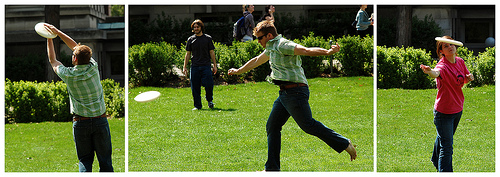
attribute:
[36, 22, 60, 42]
frisbee — plastic, white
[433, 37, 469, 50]
frisbee — white, yellow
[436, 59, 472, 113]
shirt — pink, red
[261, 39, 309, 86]
shirt — green, white, green plaid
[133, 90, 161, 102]
frisbee — white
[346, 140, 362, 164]
foot — bare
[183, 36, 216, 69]
shirt — black, dark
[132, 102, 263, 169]
grass — green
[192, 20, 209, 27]
hair — brown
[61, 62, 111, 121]
shirt — green plaid